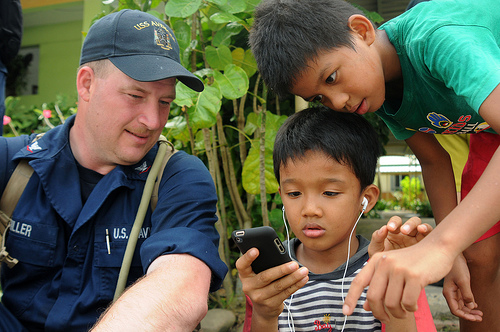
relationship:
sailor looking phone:
[2, 6, 226, 330] [228, 218, 301, 279]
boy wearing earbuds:
[198, 102, 417, 327] [274, 191, 369, 323]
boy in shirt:
[233, 105, 436, 331] [277, 238, 382, 328]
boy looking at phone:
[233, 105, 436, 331] [228, 213, 299, 293]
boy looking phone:
[233, 105, 436, 331] [231, 220, 300, 295]